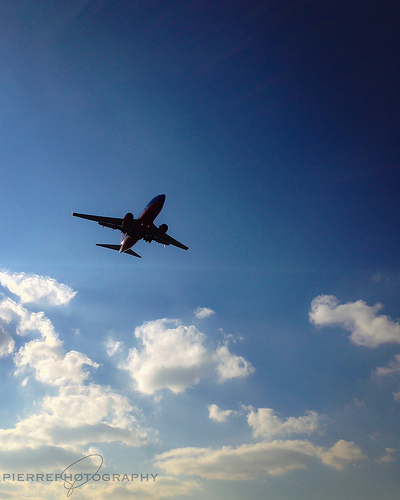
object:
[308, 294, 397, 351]
cloud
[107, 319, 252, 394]
cloud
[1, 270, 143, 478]
cloud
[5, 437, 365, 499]
cloud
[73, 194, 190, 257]
airplane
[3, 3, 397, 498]
sky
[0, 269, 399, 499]
clouds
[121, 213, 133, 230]
engine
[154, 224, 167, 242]
engine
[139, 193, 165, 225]
nose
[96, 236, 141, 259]
tail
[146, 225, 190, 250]
wing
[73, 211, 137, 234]
wing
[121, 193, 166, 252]
body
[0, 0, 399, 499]
photo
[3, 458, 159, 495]
logo